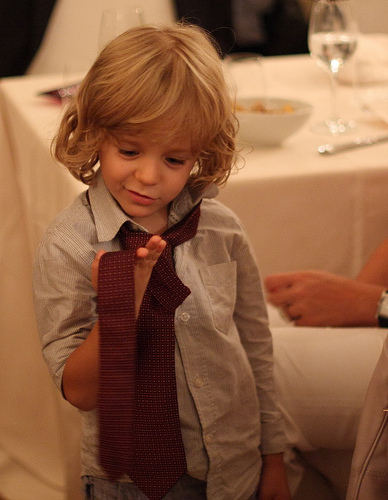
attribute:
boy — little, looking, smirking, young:
[32, 23, 290, 499]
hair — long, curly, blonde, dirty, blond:
[50, 23, 250, 195]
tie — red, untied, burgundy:
[97, 208, 202, 498]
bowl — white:
[233, 93, 314, 151]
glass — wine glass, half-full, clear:
[307, 0, 360, 135]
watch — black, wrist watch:
[375, 288, 387, 330]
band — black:
[377, 310, 387, 333]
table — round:
[3, 54, 388, 499]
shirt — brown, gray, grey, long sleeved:
[35, 171, 287, 500]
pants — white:
[269, 327, 383, 494]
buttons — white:
[178, 310, 217, 446]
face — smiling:
[101, 105, 205, 219]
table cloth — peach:
[3, 32, 387, 498]